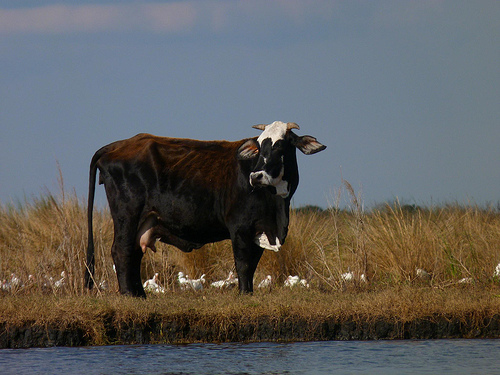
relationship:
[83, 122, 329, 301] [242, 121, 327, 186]
cow has head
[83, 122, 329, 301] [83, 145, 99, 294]
cow has tail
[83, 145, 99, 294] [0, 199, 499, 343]
tail touches grass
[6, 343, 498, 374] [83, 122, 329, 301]
water next to cow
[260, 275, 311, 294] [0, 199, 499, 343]
trash in grass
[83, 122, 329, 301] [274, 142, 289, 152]
cow has eye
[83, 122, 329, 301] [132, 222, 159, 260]
cow has utters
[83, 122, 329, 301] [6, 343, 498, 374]
cow next to water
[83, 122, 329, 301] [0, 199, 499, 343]
cow standing in grass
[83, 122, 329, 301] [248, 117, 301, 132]
cow has horns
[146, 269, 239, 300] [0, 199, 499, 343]
birds in grass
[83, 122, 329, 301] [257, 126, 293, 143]
cow has white spot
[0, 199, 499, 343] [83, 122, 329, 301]
grass near cow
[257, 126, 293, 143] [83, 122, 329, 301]
white spot on cow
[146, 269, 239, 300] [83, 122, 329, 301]
birds below cow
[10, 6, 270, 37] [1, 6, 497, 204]
clouds in sky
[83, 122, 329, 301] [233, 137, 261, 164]
cow has ear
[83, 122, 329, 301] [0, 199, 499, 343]
cow in grass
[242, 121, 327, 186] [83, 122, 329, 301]
head of cow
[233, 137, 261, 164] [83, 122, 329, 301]
ear of cow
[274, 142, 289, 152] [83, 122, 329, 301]
eye of cow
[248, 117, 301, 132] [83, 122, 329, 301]
horns on cow